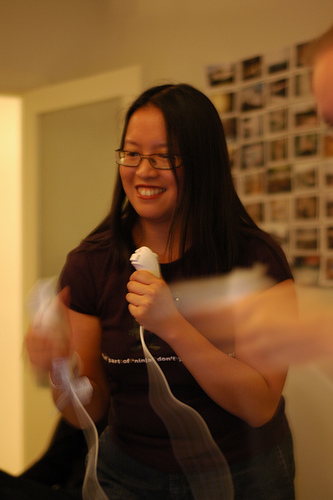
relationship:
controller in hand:
[128, 245, 160, 279] [126, 268, 170, 336]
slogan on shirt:
[85, 328, 223, 388] [56, 215, 295, 475]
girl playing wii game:
[24, 82, 298, 496] [102, 232, 173, 301]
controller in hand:
[130, 246, 161, 278] [98, 273, 179, 334]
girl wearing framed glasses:
[24, 82, 298, 496] [114, 147, 184, 170]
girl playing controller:
[24, 82, 298, 496] [130, 246, 161, 278]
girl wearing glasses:
[24, 82, 298, 496] [115, 148, 184, 169]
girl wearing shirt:
[24, 82, 298, 496] [61, 236, 288, 455]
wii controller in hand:
[130, 245, 162, 279] [125, 266, 174, 334]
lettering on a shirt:
[97, 348, 180, 365] [56, 215, 295, 475]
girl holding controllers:
[24, 82, 298, 496] [3, 245, 225, 365]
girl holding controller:
[24, 82, 298, 496] [30, 292, 80, 348]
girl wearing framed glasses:
[24, 82, 298, 496] [107, 143, 185, 170]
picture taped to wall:
[240, 54, 262, 80] [144, 39, 331, 387]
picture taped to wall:
[239, 80, 264, 113] [144, 39, 331, 387]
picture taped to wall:
[268, 107, 289, 132] [144, 39, 331, 387]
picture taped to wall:
[241, 113, 261, 137] [144, 39, 331, 387]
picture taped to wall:
[269, 133, 288, 161] [144, 39, 331, 387]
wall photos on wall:
[199, 54, 332, 211] [149, 27, 322, 146]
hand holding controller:
[125, 266, 174, 334] [130, 244, 164, 279]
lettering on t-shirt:
[101, 351, 182, 363] [72, 258, 140, 378]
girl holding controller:
[24, 82, 298, 496] [114, 241, 183, 315]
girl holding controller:
[24, 82, 298, 496] [29, 271, 88, 346]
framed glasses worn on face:
[114, 147, 184, 170] [114, 97, 206, 229]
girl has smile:
[24, 82, 298, 496] [132, 181, 170, 199]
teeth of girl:
[134, 187, 166, 197] [24, 82, 298, 496]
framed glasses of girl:
[114, 147, 184, 170] [24, 82, 298, 496]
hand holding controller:
[125, 266, 174, 334] [128, 242, 168, 316]